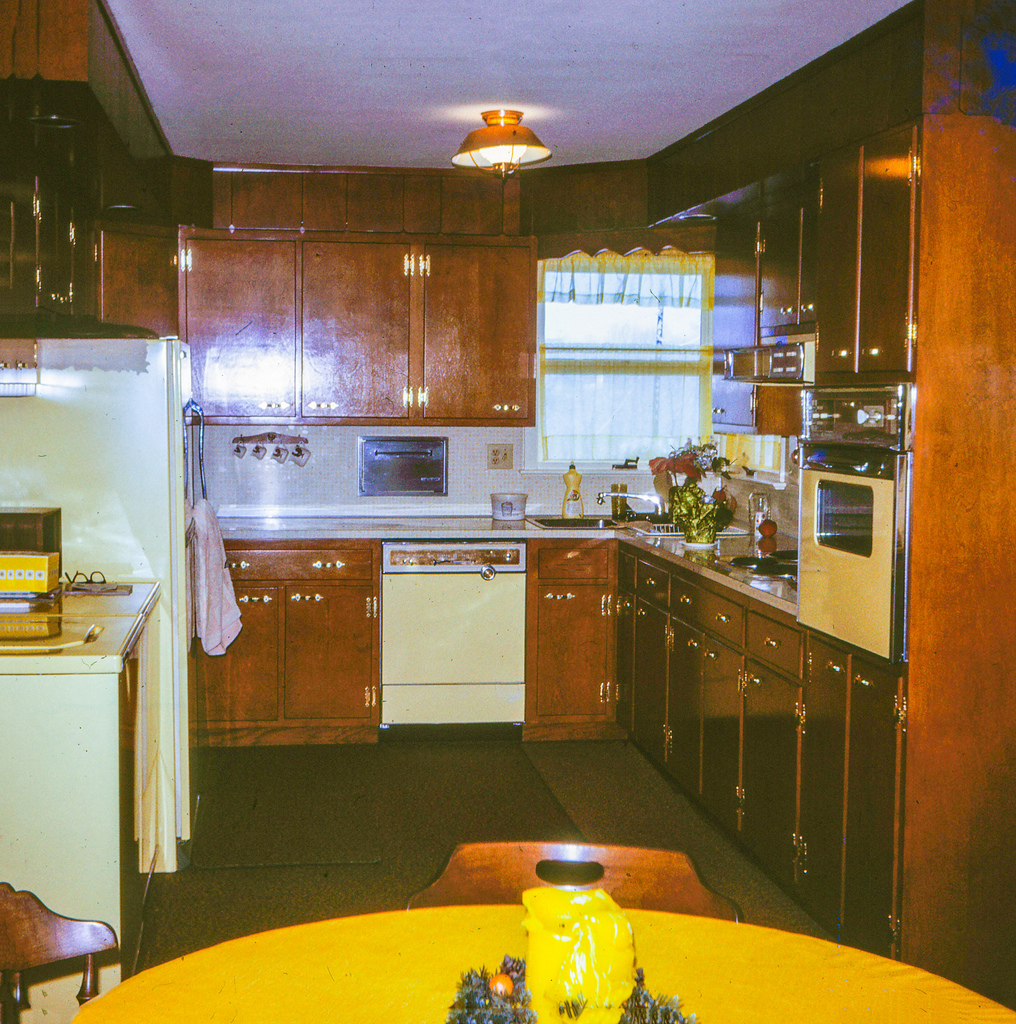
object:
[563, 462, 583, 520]
bottle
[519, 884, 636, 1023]
candle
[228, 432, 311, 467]
cup holder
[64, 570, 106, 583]
glasses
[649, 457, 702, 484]
red plants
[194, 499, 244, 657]
kitchen towel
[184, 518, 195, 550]
refrigerator handle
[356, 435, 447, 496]
door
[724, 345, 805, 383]
stove hood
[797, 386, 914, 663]
oven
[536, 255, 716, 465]
curtains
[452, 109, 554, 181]
light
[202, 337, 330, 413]
light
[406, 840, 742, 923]
chair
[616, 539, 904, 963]
line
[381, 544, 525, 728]
oven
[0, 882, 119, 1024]
chair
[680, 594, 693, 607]
handle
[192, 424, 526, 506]
wall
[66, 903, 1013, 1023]
table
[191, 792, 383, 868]
orange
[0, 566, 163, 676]
counter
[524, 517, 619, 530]
sink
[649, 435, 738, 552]
pots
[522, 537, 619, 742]
cabinets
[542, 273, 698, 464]
window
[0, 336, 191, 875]
refrigerator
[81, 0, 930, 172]
ceiling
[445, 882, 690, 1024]
item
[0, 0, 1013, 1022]
kitchen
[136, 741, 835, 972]
ground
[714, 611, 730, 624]
handle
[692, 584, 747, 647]
drawer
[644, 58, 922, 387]
cabinets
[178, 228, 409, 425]
cabinet doors